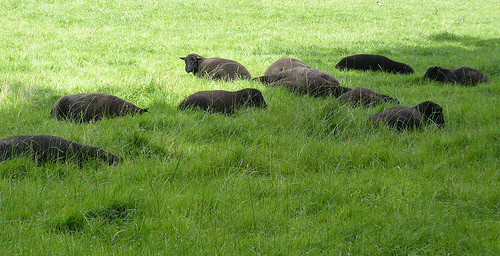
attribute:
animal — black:
[3, 131, 118, 167]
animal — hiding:
[373, 101, 444, 129]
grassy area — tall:
[219, 113, 365, 179]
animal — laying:
[52, 90, 152, 122]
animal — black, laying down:
[335, 52, 415, 74]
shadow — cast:
[0, 32, 497, 253]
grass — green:
[183, 115, 388, 254]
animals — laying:
[0, 24, 497, 186]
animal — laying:
[44, 89, 146, 126]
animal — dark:
[162, 76, 255, 133]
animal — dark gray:
[369, 102, 443, 130]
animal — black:
[51, 92, 146, 122]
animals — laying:
[162, 45, 490, 143]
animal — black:
[369, 100, 449, 136]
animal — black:
[422, 63, 487, 85]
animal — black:
[337, 48, 416, 77]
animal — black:
[173, 85, 270, 117]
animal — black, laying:
[258, 65, 350, 97]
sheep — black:
[177, 87, 267, 114]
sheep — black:
[181, 52, 251, 77]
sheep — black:
[365, 101, 443, 130]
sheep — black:
[52, 92, 148, 123]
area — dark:
[45, 192, 146, 240]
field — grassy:
[2, 1, 493, 254]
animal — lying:
[268, 59, 345, 106]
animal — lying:
[331, 47, 419, 78]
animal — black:
[334, 82, 396, 107]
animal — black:
[371, 100, 449, 132]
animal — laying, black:
[265, 53, 349, 101]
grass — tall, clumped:
[305, 82, 374, 144]